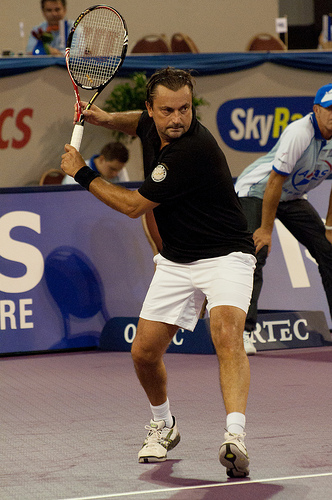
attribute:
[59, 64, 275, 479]
man — getting ready to swi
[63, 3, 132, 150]
racket — being swung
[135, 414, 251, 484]
shoes — black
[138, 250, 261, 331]
shorts — white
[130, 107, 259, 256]
shirt — black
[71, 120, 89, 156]
handle — white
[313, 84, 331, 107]
hat — blue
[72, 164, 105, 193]
wristband — black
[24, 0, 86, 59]
man — sitting in backgroun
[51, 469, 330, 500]
line — white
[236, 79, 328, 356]
man — bending forward, bending over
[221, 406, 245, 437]
sock — white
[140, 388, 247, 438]
socks — long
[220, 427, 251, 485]
foot — lifted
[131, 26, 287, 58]
chairs — empty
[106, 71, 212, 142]
plant — hanging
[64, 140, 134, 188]
man — looking down, seated